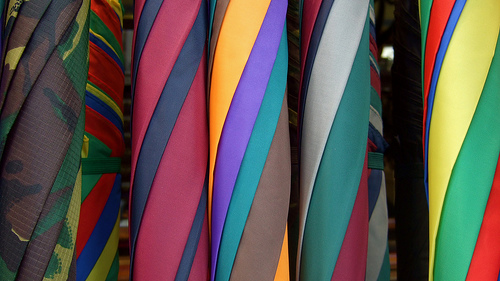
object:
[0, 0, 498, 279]
umbrellas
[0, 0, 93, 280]
tie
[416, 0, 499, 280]
umbrella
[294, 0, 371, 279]
umbrella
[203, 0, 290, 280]
umbrella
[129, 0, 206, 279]
umbrella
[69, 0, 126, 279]
umbrella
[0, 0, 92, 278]
umbrella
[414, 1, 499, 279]
tie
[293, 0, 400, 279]
tie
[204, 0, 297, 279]
tie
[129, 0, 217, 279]
tie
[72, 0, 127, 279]
tie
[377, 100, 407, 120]
ground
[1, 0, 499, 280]
ties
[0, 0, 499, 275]
fabric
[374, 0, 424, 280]
surface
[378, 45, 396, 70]
light source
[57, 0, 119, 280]
surface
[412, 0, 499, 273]
stripe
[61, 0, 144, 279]
cloth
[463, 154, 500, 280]
stripe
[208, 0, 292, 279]
striped fabric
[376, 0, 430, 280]
dark background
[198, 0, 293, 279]
umbrella